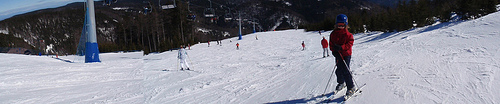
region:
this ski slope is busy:
[18, 10, 330, 100]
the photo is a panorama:
[16, 8, 393, 97]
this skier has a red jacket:
[317, 10, 378, 95]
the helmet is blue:
[313, 5, 393, 100]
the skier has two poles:
[313, 16, 378, 93]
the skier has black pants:
[302, 6, 383, 96]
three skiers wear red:
[289, 15, 460, 98]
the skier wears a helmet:
[302, 13, 427, 97]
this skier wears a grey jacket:
[163, 33, 203, 88]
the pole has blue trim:
[70, 6, 121, 86]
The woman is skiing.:
[318, 12, 366, 102]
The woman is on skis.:
[320, 13, 365, 103]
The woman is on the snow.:
[321, 11, 369, 102]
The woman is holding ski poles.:
[321, 11, 366, 103]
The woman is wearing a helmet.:
[321, 11, 364, 102]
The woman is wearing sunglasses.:
[316, 9, 368, 101]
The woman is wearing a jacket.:
[316, 16, 366, 103]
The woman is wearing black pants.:
[318, 8, 366, 99]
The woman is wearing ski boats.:
[324, 16, 369, 101]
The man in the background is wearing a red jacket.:
[319, 36, 329, 58]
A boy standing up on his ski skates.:
[312, 4, 374, 97]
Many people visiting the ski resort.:
[140, 15, 498, 99]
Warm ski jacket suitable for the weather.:
[329, 28, 361, 58]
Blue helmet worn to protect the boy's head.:
[330, 15, 365, 28]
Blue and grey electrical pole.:
[68, 0, 111, 70]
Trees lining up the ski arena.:
[106, 4, 210, 46]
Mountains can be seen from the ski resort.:
[2, 2, 87, 58]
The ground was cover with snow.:
[2, 58, 319, 100]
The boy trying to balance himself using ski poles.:
[326, 15, 367, 100]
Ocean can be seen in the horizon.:
[0, 1, 56, 11]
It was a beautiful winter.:
[11, 3, 499, 97]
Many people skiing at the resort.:
[175, 15, 462, 94]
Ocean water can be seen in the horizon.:
[1, 0, 67, 10]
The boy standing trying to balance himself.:
[326, 7, 363, 102]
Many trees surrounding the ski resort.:
[110, 1, 197, 41]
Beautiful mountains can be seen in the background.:
[0, 0, 80, 55]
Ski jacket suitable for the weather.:
[327, 30, 350, 57]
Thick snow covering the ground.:
[0, 27, 496, 100]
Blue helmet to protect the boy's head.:
[330, 14, 355, 30]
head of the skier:
[324, 11, 357, 33]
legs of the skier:
[325, 61, 359, 86]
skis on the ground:
[316, 80, 359, 102]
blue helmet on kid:
[327, 13, 359, 29]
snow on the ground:
[262, 70, 295, 94]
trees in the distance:
[115, 18, 170, 43]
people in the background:
[208, 21, 330, 84]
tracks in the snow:
[217, 59, 292, 101]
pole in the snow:
[56, 5, 110, 59]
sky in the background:
[0, 3, 21, 17]